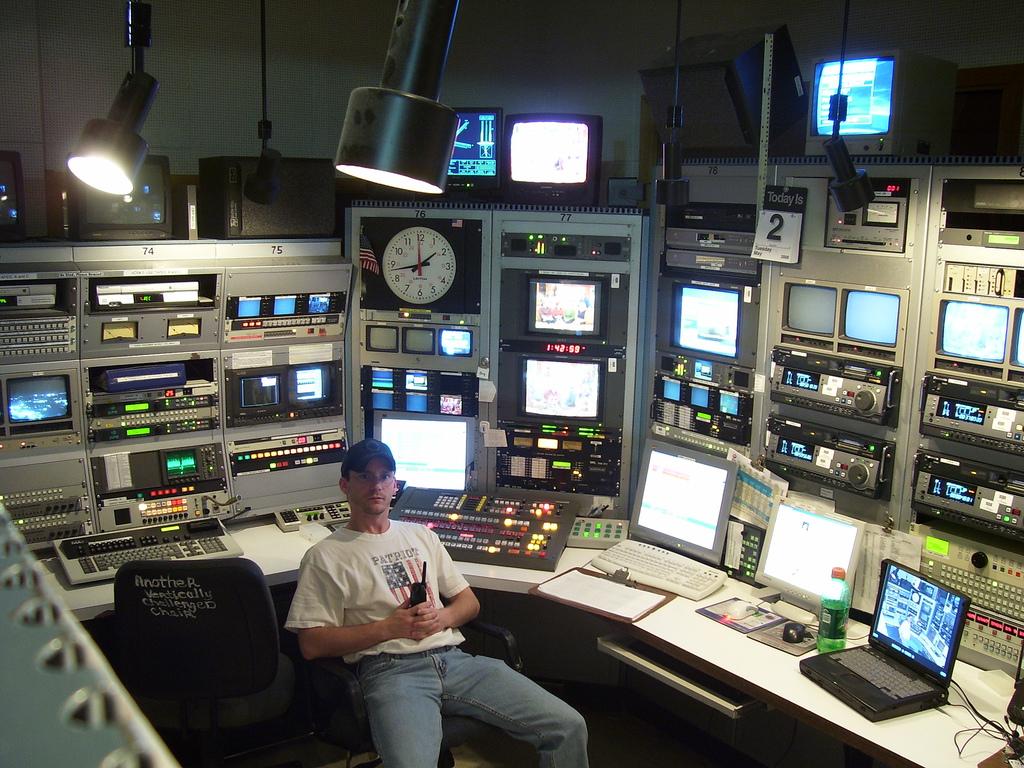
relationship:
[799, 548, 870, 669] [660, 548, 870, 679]
drink on desk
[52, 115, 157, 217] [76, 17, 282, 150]
light hanging from ceiling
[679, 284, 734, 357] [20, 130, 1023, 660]
monitor has structure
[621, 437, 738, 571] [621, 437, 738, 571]
screen on monitor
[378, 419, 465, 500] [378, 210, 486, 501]
monitor on structure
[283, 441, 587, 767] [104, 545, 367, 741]
man in chair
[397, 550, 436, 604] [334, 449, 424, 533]
radio held by man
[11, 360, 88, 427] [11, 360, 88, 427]
screen on monitor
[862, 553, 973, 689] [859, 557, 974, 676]
screen on monitor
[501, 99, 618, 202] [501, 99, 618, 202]
screen on monitor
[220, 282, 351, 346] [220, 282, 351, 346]
screen on monitor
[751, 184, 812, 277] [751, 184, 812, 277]
number on calendar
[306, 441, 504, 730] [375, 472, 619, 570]
man in front of control board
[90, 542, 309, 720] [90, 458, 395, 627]
chair against desk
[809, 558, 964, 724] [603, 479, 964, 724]
laptop on desk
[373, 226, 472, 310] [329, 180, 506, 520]
clock on control board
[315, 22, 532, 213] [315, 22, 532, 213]
lamp from ceiling